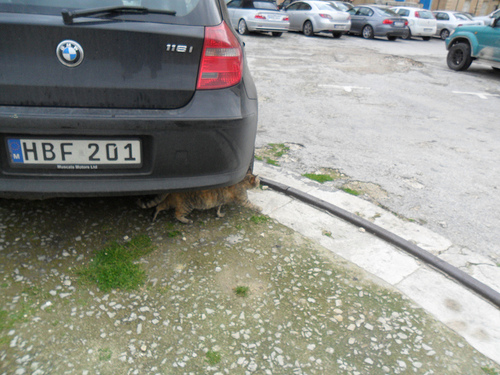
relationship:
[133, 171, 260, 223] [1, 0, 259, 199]
cat walking under car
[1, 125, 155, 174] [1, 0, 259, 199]
license plate on back of car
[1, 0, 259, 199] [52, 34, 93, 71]
car has bmw logo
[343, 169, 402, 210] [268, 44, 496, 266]
pot holes on street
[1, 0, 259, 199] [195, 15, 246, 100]
car has brake light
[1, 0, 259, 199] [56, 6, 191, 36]
car has rear windshielf wipe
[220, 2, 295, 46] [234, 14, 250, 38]
vehicle has tire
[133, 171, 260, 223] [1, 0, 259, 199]
cat under car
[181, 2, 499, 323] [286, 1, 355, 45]
parking lot has car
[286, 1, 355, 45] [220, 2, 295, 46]
car parked to vehicle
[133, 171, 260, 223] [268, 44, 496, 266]
cat walking to street